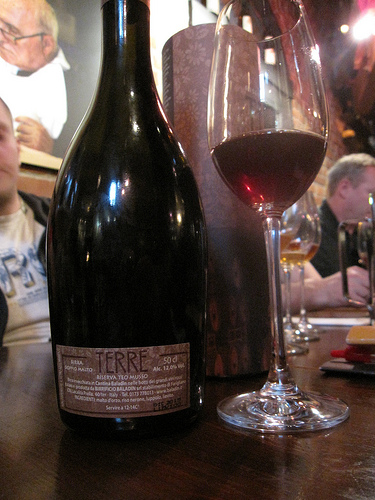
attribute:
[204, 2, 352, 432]
glass — clear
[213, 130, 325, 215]
wine — red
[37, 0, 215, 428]
bottle — dark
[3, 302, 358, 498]
table — dark, brown, wood, wooden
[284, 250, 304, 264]
wine — white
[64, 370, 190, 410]
words — white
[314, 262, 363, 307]
hand — human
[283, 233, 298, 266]
wine — white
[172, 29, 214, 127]
print — floral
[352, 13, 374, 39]
lights — bright